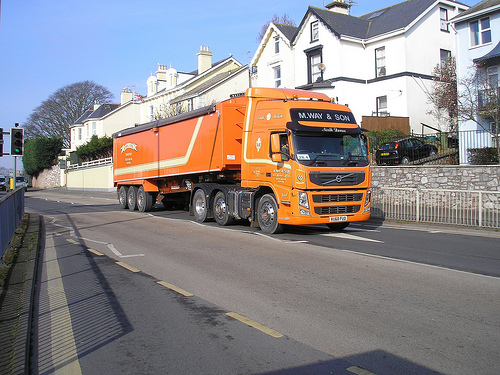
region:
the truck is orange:
[28, 57, 411, 283]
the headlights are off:
[290, 178, 414, 221]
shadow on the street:
[22, 205, 132, 370]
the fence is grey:
[0, 164, 57, 315]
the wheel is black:
[227, 182, 287, 242]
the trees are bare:
[2, 65, 115, 143]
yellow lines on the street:
[0, 227, 315, 360]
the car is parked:
[356, 122, 448, 169]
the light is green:
[1, 120, 34, 170]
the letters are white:
[272, 104, 359, 131]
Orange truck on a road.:
[107, 84, 374, 236]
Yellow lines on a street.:
[42, 225, 298, 350]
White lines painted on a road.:
[40, 211, 150, 261]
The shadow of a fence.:
[3, 210, 136, 373]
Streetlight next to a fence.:
[1, 118, 23, 185]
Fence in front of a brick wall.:
[376, 182, 498, 231]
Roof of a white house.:
[267, 3, 449, 45]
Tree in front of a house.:
[425, 54, 498, 149]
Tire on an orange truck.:
[189, 183, 210, 225]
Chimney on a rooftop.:
[193, 43, 212, 78]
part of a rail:
[447, 205, 467, 234]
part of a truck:
[323, 167, 328, 183]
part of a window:
[313, 133, 323, 147]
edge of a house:
[397, 75, 407, 93]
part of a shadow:
[96, 320, 117, 345]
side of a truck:
[195, 130, 205, 138]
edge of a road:
[250, 300, 288, 330]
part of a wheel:
[252, 218, 269, 221]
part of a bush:
[443, 103, 446, 118]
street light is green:
[1, 115, 33, 190]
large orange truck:
[117, 77, 379, 241]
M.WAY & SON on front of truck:
[288, 104, 357, 133]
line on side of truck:
[108, 110, 215, 177]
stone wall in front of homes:
[373, 163, 498, 226]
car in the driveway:
[372, 120, 447, 168]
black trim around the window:
[300, 40, 328, 85]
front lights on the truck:
[278, 188, 383, 228]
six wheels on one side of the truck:
[95, 173, 290, 238]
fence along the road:
[378, 181, 498, 220]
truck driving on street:
[97, 61, 394, 212]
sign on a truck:
[281, 105, 358, 125]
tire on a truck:
[252, 187, 277, 237]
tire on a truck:
[210, 185, 233, 226]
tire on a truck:
[191, 180, 207, 226]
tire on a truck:
[132, 186, 148, 212]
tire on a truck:
[121, 175, 136, 211]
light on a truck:
[293, 185, 319, 207]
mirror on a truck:
[265, 125, 283, 165]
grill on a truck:
[307, 189, 370, 216]